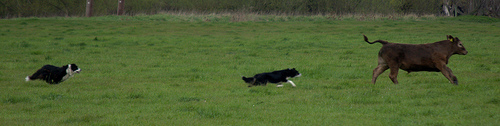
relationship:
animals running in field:
[16, 32, 472, 92] [2, 13, 499, 124]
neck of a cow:
[445, 40, 459, 64] [359, 24, 469, 88]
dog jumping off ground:
[23, 57, 82, 86] [2, 15, 499, 123]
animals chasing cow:
[240, 68, 302, 87] [358, 32, 470, 87]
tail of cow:
[355, 28, 385, 50] [353, 13, 486, 97]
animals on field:
[240, 68, 302, 87] [215, 87, 428, 124]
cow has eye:
[352, 26, 489, 100] [285, 62, 311, 85]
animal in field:
[359, 32, 473, 93] [79, 40, 457, 113]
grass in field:
[136, 57, 169, 82] [34, 11, 355, 56]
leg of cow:
[387, 60, 400, 89] [355, 27, 482, 88]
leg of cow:
[371, 65, 384, 85] [305, 39, 485, 104]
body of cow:
[377, 48, 443, 72] [359, 24, 469, 88]